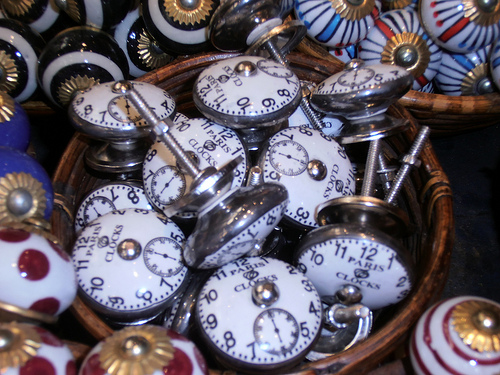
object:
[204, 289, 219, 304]
10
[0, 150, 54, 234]
ball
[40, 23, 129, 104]
knob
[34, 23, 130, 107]
ball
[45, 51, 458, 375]
basket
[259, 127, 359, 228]
clock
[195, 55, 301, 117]
clock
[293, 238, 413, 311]
clock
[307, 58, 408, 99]
clock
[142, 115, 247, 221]
clock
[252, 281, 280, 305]
clock button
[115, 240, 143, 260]
clock button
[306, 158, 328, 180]
clock button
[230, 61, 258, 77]
clock button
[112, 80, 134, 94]
clock button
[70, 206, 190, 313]
clock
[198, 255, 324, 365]
clock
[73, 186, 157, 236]
clock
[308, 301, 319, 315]
number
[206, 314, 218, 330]
number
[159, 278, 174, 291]
number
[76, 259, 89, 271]
number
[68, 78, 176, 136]
clock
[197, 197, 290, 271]
clock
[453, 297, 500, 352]
brass top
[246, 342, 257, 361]
seven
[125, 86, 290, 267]
screw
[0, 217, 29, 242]
polka dots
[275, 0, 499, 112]
basket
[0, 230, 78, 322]
ball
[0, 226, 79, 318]
know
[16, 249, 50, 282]
dot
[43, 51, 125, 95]
stripe